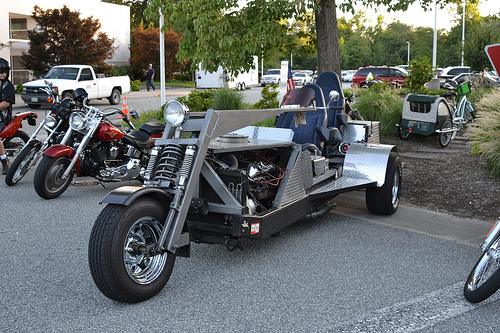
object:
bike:
[32, 87, 166, 199]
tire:
[463, 232, 499, 303]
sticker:
[250, 222, 261, 235]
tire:
[365, 152, 403, 215]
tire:
[32, 155, 74, 200]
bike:
[0, 110, 38, 163]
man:
[142, 63, 155, 92]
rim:
[127, 240, 158, 260]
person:
[0, 58, 15, 176]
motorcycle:
[462, 216, 499, 303]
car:
[194, 55, 258, 91]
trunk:
[316, 10, 337, 60]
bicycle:
[395, 70, 480, 147]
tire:
[88, 197, 177, 304]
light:
[69, 111, 87, 131]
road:
[336, 230, 478, 331]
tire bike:
[7, 132, 38, 184]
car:
[18, 65, 131, 110]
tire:
[4, 140, 43, 187]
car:
[350, 65, 414, 89]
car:
[261, 69, 282, 87]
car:
[437, 66, 473, 83]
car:
[291, 73, 314, 86]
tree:
[99, 0, 478, 86]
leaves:
[118, 0, 287, 72]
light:
[163, 100, 190, 128]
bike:
[86, 71, 403, 303]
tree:
[331, 10, 500, 72]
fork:
[60, 99, 104, 180]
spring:
[153, 142, 185, 187]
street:
[5, 85, 312, 136]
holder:
[394, 92, 458, 148]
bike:
[4, 79, 126, 187]